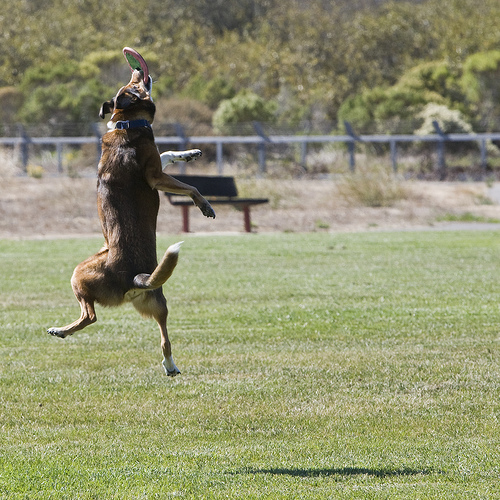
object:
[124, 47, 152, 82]
frisbee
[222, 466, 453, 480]
shadow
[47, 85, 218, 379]
dog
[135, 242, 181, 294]
tail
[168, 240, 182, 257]
white tip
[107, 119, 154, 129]
collar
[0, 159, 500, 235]
bench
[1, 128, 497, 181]
fence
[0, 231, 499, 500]
grass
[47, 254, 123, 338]
hind leg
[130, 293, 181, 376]
hind leg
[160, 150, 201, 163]
front leg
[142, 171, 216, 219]
front leg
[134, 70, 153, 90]
mouth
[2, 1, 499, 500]
park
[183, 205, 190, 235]
post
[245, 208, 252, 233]
post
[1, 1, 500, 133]
trees